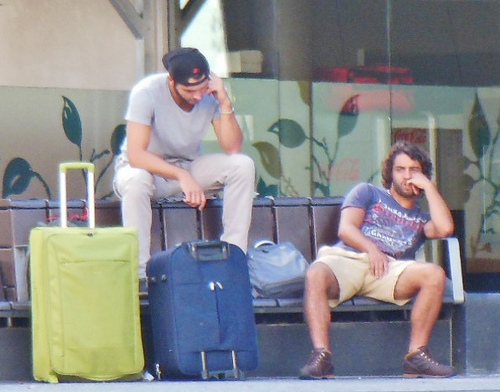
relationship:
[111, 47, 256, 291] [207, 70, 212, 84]
man talking on cellphone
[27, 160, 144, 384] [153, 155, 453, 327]
suitcase in front of bench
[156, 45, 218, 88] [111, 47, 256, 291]
backwards hat on man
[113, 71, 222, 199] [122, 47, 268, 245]
gray shirt on man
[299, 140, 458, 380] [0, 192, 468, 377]
man sitting on bench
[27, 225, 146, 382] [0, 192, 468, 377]
suitcase in front of bench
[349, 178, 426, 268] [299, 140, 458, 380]
gray shirt on man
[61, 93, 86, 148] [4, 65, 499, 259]
leave on wall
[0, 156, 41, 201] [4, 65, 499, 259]
leave on wall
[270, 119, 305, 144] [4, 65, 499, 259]
leave on wall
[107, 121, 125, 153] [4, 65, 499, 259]
leave on wall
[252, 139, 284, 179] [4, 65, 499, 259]
leave on wall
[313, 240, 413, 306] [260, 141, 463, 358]
shorts on man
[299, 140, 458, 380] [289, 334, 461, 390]
man has shoes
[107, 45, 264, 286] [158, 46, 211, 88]
man wearing backwards hat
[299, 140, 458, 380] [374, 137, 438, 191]
man with hair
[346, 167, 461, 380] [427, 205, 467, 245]
man has elbow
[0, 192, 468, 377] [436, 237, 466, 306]
bench has arm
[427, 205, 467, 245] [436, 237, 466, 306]
elbow resting on arm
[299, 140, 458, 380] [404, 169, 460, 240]
man has hand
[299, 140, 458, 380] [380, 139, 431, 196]
man has head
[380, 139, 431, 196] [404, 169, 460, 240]
head resting on hand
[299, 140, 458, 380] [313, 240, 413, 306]
man wearing shorts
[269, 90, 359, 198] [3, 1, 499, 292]
leaves painted on wall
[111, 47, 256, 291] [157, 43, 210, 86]
man with cap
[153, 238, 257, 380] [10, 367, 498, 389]
suitcase on ground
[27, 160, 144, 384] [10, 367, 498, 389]
suitcase on ground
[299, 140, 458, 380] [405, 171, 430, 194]
man leaning on hand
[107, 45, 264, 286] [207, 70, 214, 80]
man talking on cellphone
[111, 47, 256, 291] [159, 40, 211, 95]
man wearing cap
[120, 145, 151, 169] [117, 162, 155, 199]
elbow resting on knee